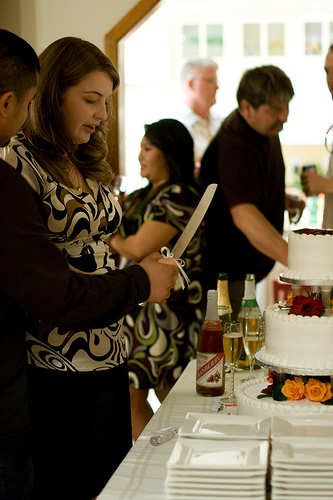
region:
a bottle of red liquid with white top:
[192, 288, 225, 395]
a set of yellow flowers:
[279, 374, 331, 406]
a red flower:
[286, 291, 323, 326]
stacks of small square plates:
[167, 410, 331, 498]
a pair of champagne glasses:
[217, 314, 264, 406]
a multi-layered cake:
[238, 227, 332, 429]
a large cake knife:
[153, 180, 219, 299]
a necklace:
[53, 162, 84, 192]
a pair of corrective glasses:
[186, 77, 218, 85]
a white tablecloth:
[95, 357, 328, 499]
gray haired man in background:
[177, 54, 222, 153]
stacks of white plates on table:
[162, 406, 330, 499]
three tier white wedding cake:
[239, 222, 331, 432]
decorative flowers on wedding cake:
[269, 290, 331, 402]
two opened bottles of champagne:
[210, 267, 264, 354]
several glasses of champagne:
[217, 307, 267, 414]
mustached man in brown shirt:
[214, 68, 298, 276]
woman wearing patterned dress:
[114, 109, 205, 390]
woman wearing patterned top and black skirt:
[7, 36, 140, 486]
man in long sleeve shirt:
[3, 33, 177, 476]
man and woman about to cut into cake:
[0, 17, 224, 495]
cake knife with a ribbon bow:
[146, 183, 221, 309]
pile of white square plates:
[164, 413, 330, 497]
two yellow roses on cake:
[282, 371, 331, 404]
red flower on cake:
[288, 292, 326, 315]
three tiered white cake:
[237, 224, 331, 422]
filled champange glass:
[221, 318, 245, 408]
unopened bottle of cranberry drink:
[196, 287, 225, 397]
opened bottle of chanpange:
[216, 269, 233, 319]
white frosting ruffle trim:
[276, 309, 331, 330]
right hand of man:
[121, 248, 185, 306]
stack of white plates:
[151, 427, 277, 490]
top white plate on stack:
[262, 423, 325, 467]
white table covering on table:
[116, 435, 159, 487]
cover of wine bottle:
[175, 319, 233, 406]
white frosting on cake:
[256, 309, 325, 384]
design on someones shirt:
[42, 326, 130, 383]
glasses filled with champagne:
[214, 319, 274, 365]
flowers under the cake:
[265, 370, 327, 406]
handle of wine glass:
[215, 369, 241, 407]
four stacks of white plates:
[166, 411, 331, 497]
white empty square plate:
[163, 436, 268, 469]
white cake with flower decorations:
[233, 227, 331, 413]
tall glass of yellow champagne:
[221, 318, 242, 406]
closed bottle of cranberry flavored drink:
[196, 288, 225, 396]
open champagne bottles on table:
[214, 272, 262, 331]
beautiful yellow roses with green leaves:
[276, 376, 330, 400]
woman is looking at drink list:
[30, 35, 218, 346]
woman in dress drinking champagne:
[112, 117, 203, 388]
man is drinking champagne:
[203, 61, 295, 258]